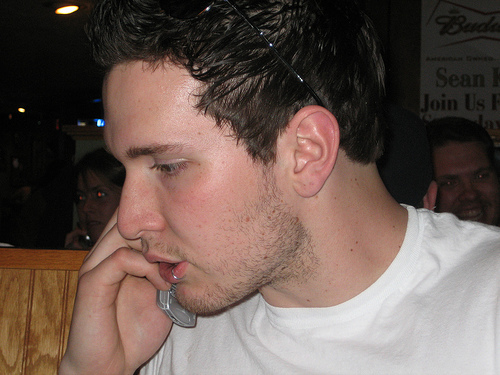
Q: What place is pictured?
A: It is a restaurant.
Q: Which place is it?
A: It is a restaurant.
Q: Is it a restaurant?
A: Yes, it is a restaurant.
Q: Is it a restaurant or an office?
A: It is a restaurant.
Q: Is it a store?
A: No, it is a restaurant.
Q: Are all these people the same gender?
A: No, they are both male and female.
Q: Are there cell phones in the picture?
A: Yes, there is a cell phone.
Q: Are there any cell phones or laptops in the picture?
A: Yes, there is a cell phone.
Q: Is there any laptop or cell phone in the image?
A: Yes, there is a cell phone.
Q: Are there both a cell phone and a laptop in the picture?
A: No, there is a cell phone but no laptops.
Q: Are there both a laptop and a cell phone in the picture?
A: No, there is a cell phone but no laptops.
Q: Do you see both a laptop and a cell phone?
A: No, there is a cell phone but no laptops.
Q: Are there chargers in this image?
A: No, there are no chargers.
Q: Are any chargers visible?
A: No, there are no chargers.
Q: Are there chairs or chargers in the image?
A: No, there are no chargers or chairs.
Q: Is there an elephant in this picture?
A: No, there are no elephants.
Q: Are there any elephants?
A: No, there are no elephants.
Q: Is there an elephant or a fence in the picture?
A: No, there are no elephants or fences.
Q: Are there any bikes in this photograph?
A: No, there are no bikes.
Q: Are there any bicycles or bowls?
A: No, there are no bicycles or bowls.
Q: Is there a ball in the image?
A: No, there are no balls.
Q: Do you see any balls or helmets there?
A: No, there are no balls or helmets.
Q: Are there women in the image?
A: Yes, there is a woman.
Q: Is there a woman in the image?
A: Yes, there is a woman.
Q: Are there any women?
A: Yes, there is a woman.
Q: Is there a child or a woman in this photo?
A: Yes, there is a woman.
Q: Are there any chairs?
A: No, there are no chairs.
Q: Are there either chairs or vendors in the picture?
A: No, there are no chairs or vendors.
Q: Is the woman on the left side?
A: Yes, the woman is on the left of the image.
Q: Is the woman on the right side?
A: No, the woman is on the left of the image.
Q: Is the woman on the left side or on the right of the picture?
A: The woman is on the left of the image.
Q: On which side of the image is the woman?
A: The woman is on the left of the image.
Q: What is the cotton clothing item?
A: The clothing item is a shirt.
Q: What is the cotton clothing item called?
A: The clothing item is a shirt.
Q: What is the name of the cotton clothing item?
A: The clothing item is a shirt.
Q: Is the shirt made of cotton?
A: Yes, the shirt is made of cotton.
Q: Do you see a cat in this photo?
A: No, there are no cats.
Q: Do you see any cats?
A: No, there are no cats.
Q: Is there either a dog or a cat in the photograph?
A: No, there are no cats or dogs.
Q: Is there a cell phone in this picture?
A: Yes, there is a cell phone.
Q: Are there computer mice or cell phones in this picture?
A: Yes, there is a cell phone.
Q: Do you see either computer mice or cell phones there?
A: Yes, there is a cell phone.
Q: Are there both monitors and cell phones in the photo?
A: No, there is a cell phone but no monitors.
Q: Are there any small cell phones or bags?
A: Yes, there is a small cell phone.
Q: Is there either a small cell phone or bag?
A: Yes, there is a small cell phone.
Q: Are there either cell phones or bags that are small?
A: Yes, the cell phone is small.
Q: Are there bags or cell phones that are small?
A: Yes, the cell phone is small.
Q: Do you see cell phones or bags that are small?
A: Yes, the cell phone is small.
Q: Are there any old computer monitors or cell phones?
A: Yes, there is an old cell phone.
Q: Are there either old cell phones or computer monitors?
A: Yes, there is an old cell phone.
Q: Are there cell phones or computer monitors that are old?
A: Yes, the cell phone is old.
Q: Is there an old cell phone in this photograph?
A: Yes, there is an old cell phone.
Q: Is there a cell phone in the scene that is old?
A: Yes, there is a cell phone that is old.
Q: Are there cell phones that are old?
A: Yes, there is a cell phone that is old.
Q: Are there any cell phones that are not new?
A: Yes, there is a old cell phone.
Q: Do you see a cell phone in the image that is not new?
A: Yes, there is a old cell phone.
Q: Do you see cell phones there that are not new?
A: Yes, there is a old cell phone.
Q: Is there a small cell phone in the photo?
A: Yes, there is a small cell phone.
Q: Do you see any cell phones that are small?
A: Yes, there is a small cell phone.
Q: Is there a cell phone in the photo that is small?
A: Yes, there is a cell phone that is small.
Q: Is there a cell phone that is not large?
A: Yes, there is a small cell phone.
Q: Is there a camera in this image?
A: No, there are no cameras.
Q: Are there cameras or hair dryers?
A: No, there are no cameras or hair dryers.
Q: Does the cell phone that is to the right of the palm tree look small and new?
A: No, the cell phone is small but old.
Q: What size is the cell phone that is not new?
A: The cellphone is small.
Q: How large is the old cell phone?
A: The cellphone is small.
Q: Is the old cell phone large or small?
A: The cell phone is small.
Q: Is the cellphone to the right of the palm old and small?
A: Yes, the cellphone is old and small.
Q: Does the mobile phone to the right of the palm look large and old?
A: No, the mobile phone is old but small.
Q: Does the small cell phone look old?
A: Yes, the cell phone is old.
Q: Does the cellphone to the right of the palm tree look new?
A: No, the cell phone is old.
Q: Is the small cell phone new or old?
A: The mobile phone is old.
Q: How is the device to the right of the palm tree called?
A: The device is a cell phone.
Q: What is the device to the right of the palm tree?
A: The device is a cell phone.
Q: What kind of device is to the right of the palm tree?
A: The device is a cell phone.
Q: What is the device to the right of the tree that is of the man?
A: The device is a cell phone.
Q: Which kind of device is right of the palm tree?
A: The device is a cell phone.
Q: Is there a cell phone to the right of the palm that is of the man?
A: Yes, there is a cell phone to the right of the palm tree.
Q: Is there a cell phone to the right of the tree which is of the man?
A: Yes, there is a cell phone to the right of the palm tree.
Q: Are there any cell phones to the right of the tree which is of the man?
A: Yes, there is a cell phone to the right of the palm tree.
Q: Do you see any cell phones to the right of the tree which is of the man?
A: Yes, there is a cell phone to the right of the palm tree.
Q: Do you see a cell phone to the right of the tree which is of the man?
A: Yes, there is a cell phone to the right of the palm tree.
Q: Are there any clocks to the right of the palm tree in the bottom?
A: No, there is a cell phone to the right of the palm.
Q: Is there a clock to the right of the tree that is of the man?
A: No, there is a cell phone to the right of the palm.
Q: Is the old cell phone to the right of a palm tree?
A: Yes, the mobile phone is to the right of a palm tree.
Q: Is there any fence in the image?
A: No, there are no fences.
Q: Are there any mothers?
A: No, there are no mothers.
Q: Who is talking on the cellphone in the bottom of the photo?
A: The man is talking on the cell phone.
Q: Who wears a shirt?
A: The man wears a shirt.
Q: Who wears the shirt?
A: The man wears a shirt.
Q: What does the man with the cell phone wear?
A: The man wears a shirt.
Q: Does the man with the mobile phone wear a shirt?
A: Yes, the man wears a shirt.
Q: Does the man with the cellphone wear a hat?
A: No, the man wears a shirt.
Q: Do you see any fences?
A: No, there are no fences.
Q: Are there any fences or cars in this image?
A: No, there are no fences or cars.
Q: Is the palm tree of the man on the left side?
A: Yes, the palm is on the left of the image.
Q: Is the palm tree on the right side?
A: No, the palm tree is on the left of the image.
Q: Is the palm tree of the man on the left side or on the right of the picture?
A: The palm tree is on the left of the image.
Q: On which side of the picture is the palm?
A: The palm is on the left of the image.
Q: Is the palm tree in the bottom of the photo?
A: Yes, the palm tree is in the bottom of the image.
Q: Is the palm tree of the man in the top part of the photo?
A: No, the palm tree is in the bottom of the image.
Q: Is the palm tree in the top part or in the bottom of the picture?
A: The palm tree is in the bottom of the image.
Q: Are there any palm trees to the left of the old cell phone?
A: Yes, there is a palm tree to the left of the mobile phone.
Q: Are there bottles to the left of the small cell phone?
A: No, there is a palm tree to the left of the cell phone.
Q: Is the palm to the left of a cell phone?
A: Yes, the palm is to the left of a cell phone.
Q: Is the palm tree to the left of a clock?
A: No, the palm tree is to the left of a cell phone.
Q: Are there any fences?
A: No, there are no fences.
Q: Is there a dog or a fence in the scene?
A: No, there are no fences or dogs.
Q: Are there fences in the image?
A: No, there are no fences.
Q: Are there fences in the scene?
A: No, there are no fences.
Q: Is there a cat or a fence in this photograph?
A: No, there are no fences or cats.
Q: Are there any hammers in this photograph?
A: No, there are no hammers.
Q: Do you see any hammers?
A: No, there are no hammers.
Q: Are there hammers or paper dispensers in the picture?
A: No, there are no hammers or paper dispensers.